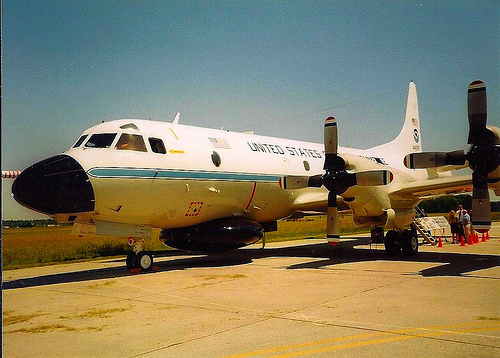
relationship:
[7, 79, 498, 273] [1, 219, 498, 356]
airplane on tarmac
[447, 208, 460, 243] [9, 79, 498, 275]
people preparing to board plane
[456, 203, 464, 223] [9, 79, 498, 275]
people preparing to board plane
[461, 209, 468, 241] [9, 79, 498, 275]
people preparing to board plane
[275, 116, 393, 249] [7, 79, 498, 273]
propeller in airplane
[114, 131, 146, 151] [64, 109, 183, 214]
window surrounds cockpit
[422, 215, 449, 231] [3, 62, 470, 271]
literature near plane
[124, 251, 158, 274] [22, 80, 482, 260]
wheels of airplane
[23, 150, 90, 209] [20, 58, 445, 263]
nose of airplane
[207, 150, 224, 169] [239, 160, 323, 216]
windows at side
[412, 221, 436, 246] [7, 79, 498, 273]
bridge on airplane